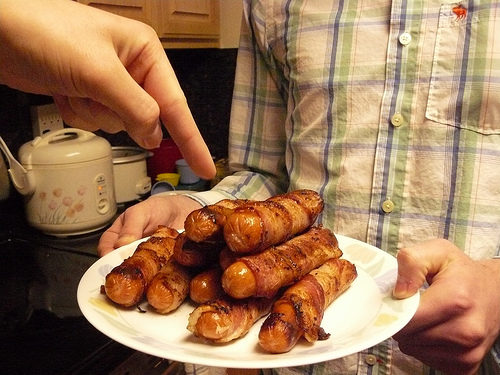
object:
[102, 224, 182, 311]
food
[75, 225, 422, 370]
plate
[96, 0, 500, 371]
person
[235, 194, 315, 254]
bacon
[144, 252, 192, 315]
hot dogs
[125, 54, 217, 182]
finger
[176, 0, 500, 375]
shirt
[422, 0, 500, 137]
pocket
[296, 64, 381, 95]
stripes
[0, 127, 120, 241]
crock pot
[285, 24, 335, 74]
plaid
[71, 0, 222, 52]
cabinet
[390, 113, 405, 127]
buttons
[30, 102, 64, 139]
outlet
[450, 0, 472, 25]
emblem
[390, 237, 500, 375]
hands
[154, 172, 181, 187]
cup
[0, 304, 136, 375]
counter